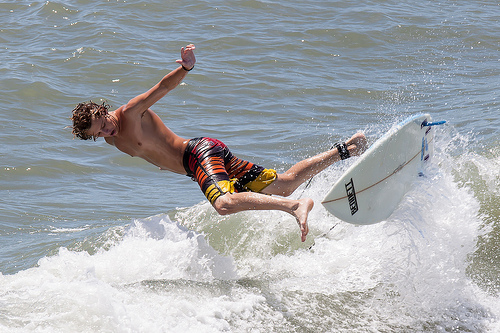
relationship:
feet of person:
[287, 129, 377, 247] [63, 76, 333, 235]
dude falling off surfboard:
[70, 43, 367, 241] [321, 112, 446, 225]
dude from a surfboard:
[70, 43, 367, 241] [321, 112, 446, 225]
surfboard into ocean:
[321, 112, 446, 225] [248, 12, 397, 101]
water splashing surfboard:
[258, 52, 433, 124] [347, 127, 483, 242]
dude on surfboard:
[70, 43, 367, 243] [320, 112, 437, 222]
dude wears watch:
[70, 43, 367, 243] [180, 62, 194, 70]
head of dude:
[62, 97, 123, 148] [70, 43, 367, 241]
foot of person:
[346, 129, 368, 155] [69, 43, 369, 241]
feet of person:
[294, 198, 316, 241] [69, 43, 369, 241]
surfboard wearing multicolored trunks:
[321, 112, 446, 225] [184, 137, 277, 202]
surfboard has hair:
[318, 103, 448, 228] [62, 94, 119, 143]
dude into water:
[70, 43, 367, 243] [1, 2, 498, 329]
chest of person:
[112, 109, 176, 172] [69, 43, 369, 241]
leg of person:
[189, 157, 332, 251] [45, 26, 372, 245]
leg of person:
[296, 138, 380, 168] [53, 59, 345, 238]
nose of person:
[96, 124, 117, 141] [53, 59, 345, 238]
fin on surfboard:
[420, 113, 443, 131] [313, 112, 444, 222]